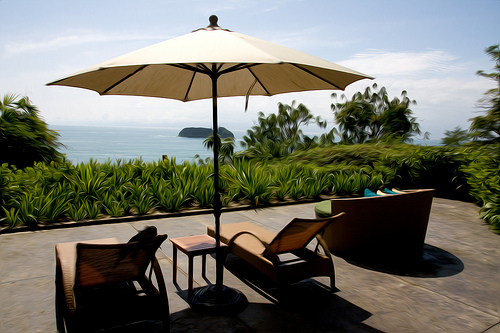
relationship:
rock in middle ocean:
[155, 116, 325, 186] [46, 124, 317, 165]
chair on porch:
[331, 177, 423, 247] [0, 202, 498, 328]